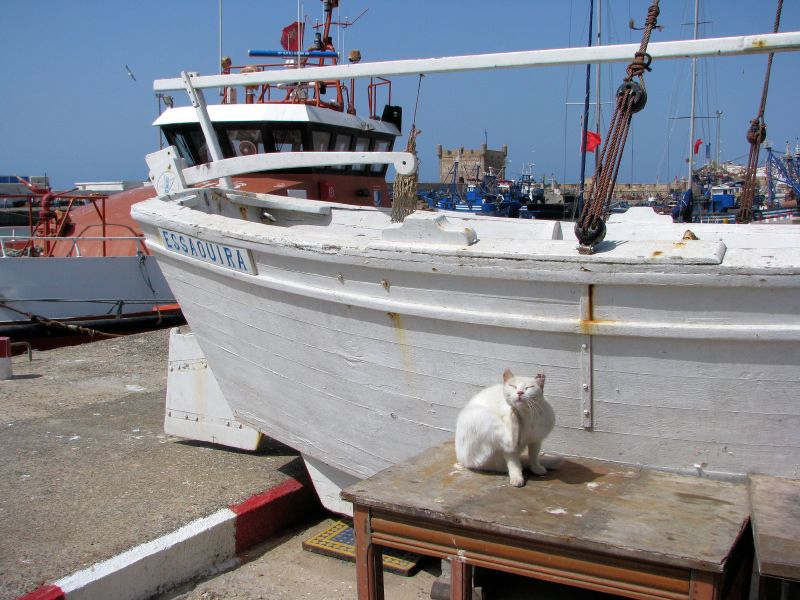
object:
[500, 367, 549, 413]
neck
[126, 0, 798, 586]
boat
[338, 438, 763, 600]
neck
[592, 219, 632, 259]
ground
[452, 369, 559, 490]
cat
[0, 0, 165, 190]
sky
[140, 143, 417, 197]
windows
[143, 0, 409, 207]
wheelhouse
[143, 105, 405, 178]
wheel house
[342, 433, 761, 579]
table top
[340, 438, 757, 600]
table